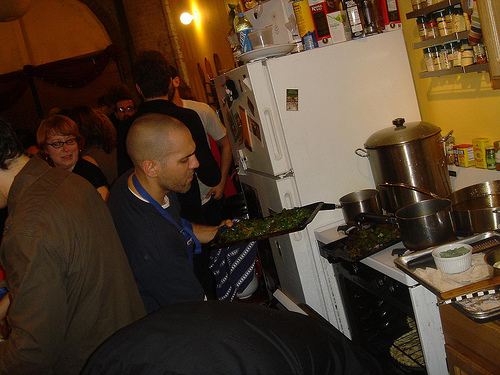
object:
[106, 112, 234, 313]
man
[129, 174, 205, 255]
lanyard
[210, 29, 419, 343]
fridge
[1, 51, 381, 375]
group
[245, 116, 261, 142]
magnets